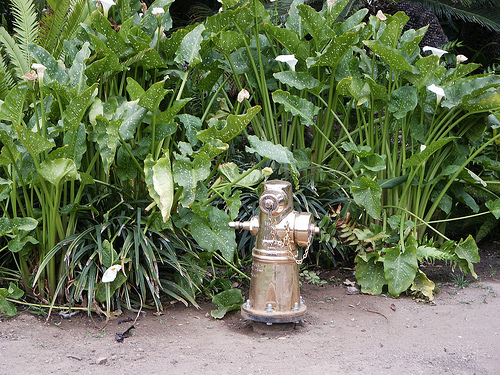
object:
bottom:
[252, 320, 300, 333]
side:
[291, 211, 321, 246]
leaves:
[382, 246, 420, 300]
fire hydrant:
[226, 179, 321, 337]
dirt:
[0, 249, 500, 375]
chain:
[269, 218, 313, 265]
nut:
[263, 197, 275, 209]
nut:
[227, 220, 241, 230]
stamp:
[260, 219, 286, 251]